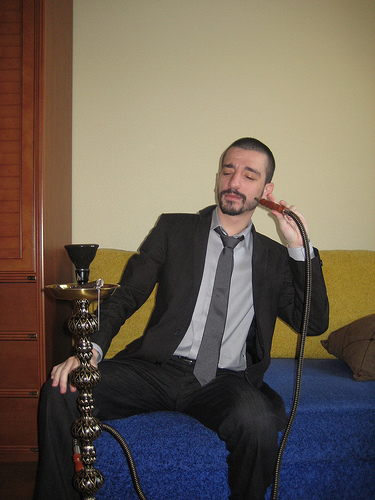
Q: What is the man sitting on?
A: Couch.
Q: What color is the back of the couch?
A: Yellow.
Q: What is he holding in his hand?
A: Pipe.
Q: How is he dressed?
A: Suit.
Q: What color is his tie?
A: Gray.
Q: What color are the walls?
A: White.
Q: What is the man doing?
A: Sitting.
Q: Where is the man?
A: Living room.